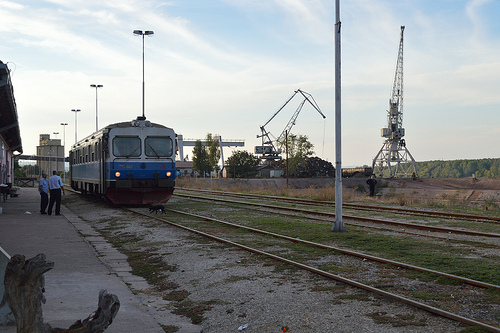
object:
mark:
[208, 255, 216, 260]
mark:
[205, 250, 213, 253]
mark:
[205, 252, 214, 255]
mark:
[201, 246, 206, 248]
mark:
[197, 254, 204, 257]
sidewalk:
[1, 185, 165, 332]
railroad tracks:
[122, 204, 500, 333]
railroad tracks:
[173, 192, 500, 249]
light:
[133, 29, 143, 36]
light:
[89, 84, 96, 87]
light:
[60, 123, 64, 126]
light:
[53, 132, 56, 134]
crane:
[368, 24, 418, 181]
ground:
[0, 182, 499, 332]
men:
[47, 169, 65, 216]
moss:
[298, 224, 318, 235]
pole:
[331, 1, 348, 231]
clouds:
[0, 0, 132, 71]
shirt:
[48, 175, 64, 190]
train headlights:
[114, 171, 121, 177]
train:
[66, 116, 177, 209]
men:
[38, 172, 50, 215]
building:
[0, 58, 23, 198]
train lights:
[165, 171, 172, 177]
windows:
[112, 134, 143, 157]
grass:
[358, 236, 384, 249]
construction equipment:
[256, 88, 326, 165]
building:
[34, 131, 68, 177]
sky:
[0, 0, 499, 173]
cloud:
[458, 1, 497, 67]